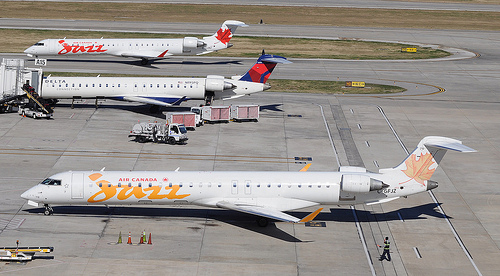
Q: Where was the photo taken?
A: At an airport.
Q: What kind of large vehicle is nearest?
A: An airplane.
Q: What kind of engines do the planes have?
A: Jet engines.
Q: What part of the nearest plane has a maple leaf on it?
A: The tail fin.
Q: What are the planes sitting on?
A: The tarmac.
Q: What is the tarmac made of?
A: Concrete.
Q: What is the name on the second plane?
A: Delta.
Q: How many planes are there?
A: Three.